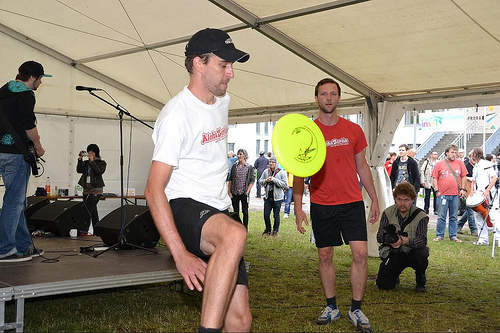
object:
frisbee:
[269, 111, 328, 178]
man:
[291, 78, 380, 333]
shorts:
[309, 200, 369, 249]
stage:
[0, 193, 224, 333]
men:
[141, 27, 253, 332]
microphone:
[75, 85, 102, 91]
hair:
[315, 78, 342, 99]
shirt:
[150, 84, 234, 213]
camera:
[383, 223, 409, 248]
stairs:
[405, 121, 499, 179]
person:
[374, 180, 429, 294]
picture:
[0, 0, 500, 333]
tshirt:
[308, 113, 369, 207]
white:
[151, 85, 234, 211]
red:
[322, 138, 359, 181]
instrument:
[21, 126, 45, 179]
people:
[430, 144, 468, 242]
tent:
[0, 0, 497, 333]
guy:
[0, 60, 47, 263]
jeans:
[0, 151, 33, 260]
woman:
[76, 143, 108, 238]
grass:
[0, 208, 499, 331]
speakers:
[93, 204, 161, 250]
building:
[380, 105, 500, 194]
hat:
[18, 60, 53, 77]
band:
[0, 56, 134, 270]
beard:
[317, 101, 338, 115]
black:
[0, 103, 27, 135]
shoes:
[316, 305, 342, 326]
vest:
[377, 203, 429, 259]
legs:
[169, 198, 249, 333]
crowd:
[227, 143, 500, 249]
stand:
[105, 112, 151, 229]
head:
[17, 60, 44, 92]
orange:
[441, 176, 455, 193]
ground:
[0, 182, 499, 332]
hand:
[173, 249, 208, 292]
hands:
[390, 234, 404, 248]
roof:
[0, 0, 500, 121]